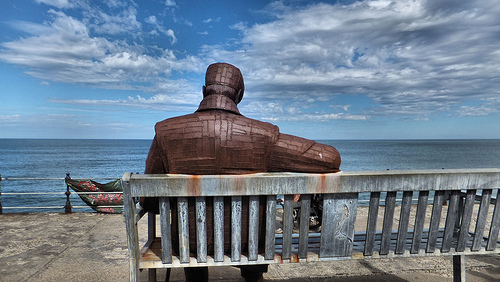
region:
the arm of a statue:
[278, 129, 343, 180]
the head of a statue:
[195, 61, 250, 111]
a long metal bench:
[117, 165, 499, 280]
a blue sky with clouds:
[4, 2, 496, 139]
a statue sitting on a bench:
[109, 53, 499, 279]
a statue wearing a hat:
[201, 60, 249, 95]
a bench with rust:
[117, 169, 494, 281]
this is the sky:
[41, 15, 179, 76]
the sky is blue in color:
[160, 0, 241, 42]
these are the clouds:
[350, 35, 466, 94]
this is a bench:
[327, 161, 489, 268]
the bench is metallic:
[390, 180, 436, 225]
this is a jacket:
[164, 86, 259, 164]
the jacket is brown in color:
[216, 121, 247, 146]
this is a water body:
[26, 133, 78, 176]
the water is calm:
[76, 128, 136, 157]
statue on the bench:
[84, 45, 325, 241]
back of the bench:
[366, 181, 445, 248]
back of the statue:
[145, 45, 310, 167]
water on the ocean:
[39, 137, 109, 162]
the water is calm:
[22, 150, 77, 170]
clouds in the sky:
[291, 0, 485, 135]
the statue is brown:
[149, 118, 273, 158]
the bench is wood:
[364, 180, 444, 250]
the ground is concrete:
[15, 234, 99, 266]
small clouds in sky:
[199, 20, 228, 50]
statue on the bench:
[152, 60, 326, 174]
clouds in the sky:
[269, 17, 454, 110]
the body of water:
[0, 127, 112, 169]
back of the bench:
[187, 188, 476, 233]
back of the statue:
[155, 73, 272, 163]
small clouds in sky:
[147, 1, 221, 38]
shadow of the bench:
[346, 264, 369, 275]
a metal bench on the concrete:
[121, 169, 498, 280]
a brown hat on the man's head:
[205, 61, 246, 86]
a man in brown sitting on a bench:
[139, 61, 341, 280]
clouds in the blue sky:
[6, 4, 180, 91]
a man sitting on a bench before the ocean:
[0, 60, 498, 280]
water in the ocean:
[2, 136, 497, 209]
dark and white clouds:
[277, 3, 498, 86]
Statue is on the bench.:
[144, 60, 342, 279]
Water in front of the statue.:
[0, 137, 499, 214]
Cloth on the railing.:
[66, 175, 123, 212]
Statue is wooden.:
[144, 60, 341, 279]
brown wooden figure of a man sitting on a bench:
[135, 59, 344, 280]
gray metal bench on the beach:
[116, 165, 498, 280]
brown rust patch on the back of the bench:
[181, 173, 205, 195]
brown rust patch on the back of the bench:
[320, 174, 326, 194]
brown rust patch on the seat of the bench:
[139, 235, 169, 262]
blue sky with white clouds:
[2, 1, 499, 135]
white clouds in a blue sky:
[1, 1, 498, 134]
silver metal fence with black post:
[2, 171, 123, 211]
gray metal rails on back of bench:
[151, 192, 318, 262]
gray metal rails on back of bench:
[363, 189, 498, 256]